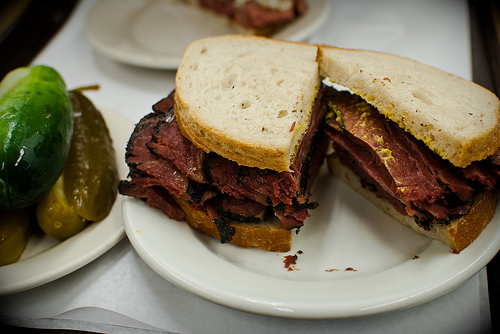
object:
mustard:
[343, 86, 451, 165]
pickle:
[36, 174, 90, 241]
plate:
[0, 108, 135, 297]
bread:
[173, 32, 322, 174]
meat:
[146, 87, 331, 210]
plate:
[81, 2, 331, 73]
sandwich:
[313, 45, 498, 255]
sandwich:
[118, 34, 333, 253]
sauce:
[280, 253, 301, 269]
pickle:
[62, 88, 118, 222]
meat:
[114, 87, 335, 226]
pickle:
[0, 63, 80, 217]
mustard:
[351, 112, 405, 193]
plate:
[119, 163, 499, 320]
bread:
[316, 44, 499, 168]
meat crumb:
[281, 253, 301, 271]